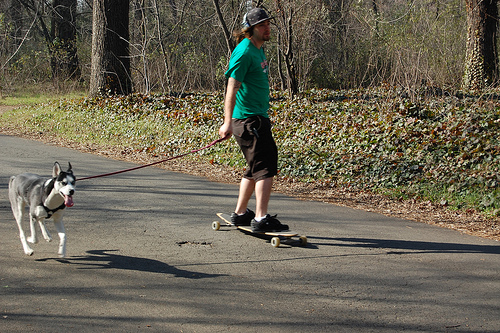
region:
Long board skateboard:
[207, 207, 309, 251]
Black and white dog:
[2, 159, 78, 260]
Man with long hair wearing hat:
[222, 5, 281, 45]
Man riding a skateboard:
[205, 3, 311, 253]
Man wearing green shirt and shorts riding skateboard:
[211, 3, 311, 248]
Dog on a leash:
[4, 118, 234, 255]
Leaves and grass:
[348, 93, 475, 195]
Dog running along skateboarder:
[5, 6, 326, 261]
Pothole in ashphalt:
[169, 233, 221, 255]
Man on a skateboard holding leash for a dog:
[4, 3, 314, 257]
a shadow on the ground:
[99, 242, 208, 284]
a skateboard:
[279, 224, 302, 238]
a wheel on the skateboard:
[263, 233, 280, 247]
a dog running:
[1, 166, 98, 261]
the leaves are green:
[302, 105, 442, 186]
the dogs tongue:
[60, 194, 77, 208]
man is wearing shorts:
[235, 128, 276, 178]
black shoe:
[245, 215, 290, 232]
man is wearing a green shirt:
[241, 65, 267, 110]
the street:
[293, 260, 432, 326]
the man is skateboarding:
[200, 9, 342, 271]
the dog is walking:
[4, 157, 94, 266]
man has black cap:
[237, 7, 267, 45]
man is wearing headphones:
[231, 10, 261, 41]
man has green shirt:
[211, 8, 318, 123]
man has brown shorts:
[235, 120, 313, 184]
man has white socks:
[230, 207, 305, 238]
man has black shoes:
[232, 200, 280, 245]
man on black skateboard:
[208, 200, 270, 240]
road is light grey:
[238, 251, 426, 328]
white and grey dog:
[15, 150, 93, 288]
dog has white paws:
[15, 215, 82, 293]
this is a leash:
[38, 112, 243, 204]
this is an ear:
[42, 151, 69, 183]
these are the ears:
[43, 150, 89, 180]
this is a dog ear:
[48, 158, 65, 183]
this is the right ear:
[48, 157, 65, 182]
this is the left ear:
[64, 161, 76, 178]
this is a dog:
[0, 151, 102, 266]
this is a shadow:
[32, 219, 238, 328]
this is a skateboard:
[206, 189, 325, 273]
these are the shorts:
[205, 106, 301, 186]